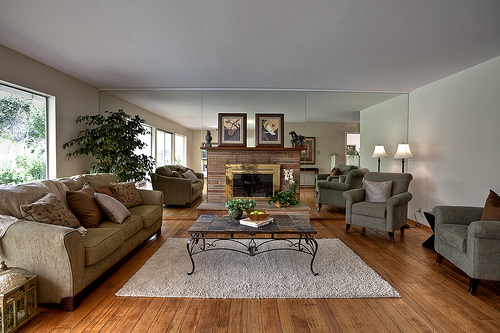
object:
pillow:
[20, 193, 82, 229]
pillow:
[110, 182, 144, 208]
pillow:
[364, 179, 392, 202]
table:
[186, 214, 318, 276]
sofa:
[0, 173, 164, 313]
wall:
[190, 122, 363, 194]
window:
[0, 81, 55, 190]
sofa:
[150, 164, 204, 208]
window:
[126, 119, 186, 190]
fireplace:
[199, 147, 307, 204]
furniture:
[2, 113, 499, 333]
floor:
[139, 206, 438, 330]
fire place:
[225, 163, 281, 203]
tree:
[62, 108, 157, 183]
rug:
[113, 237, 401, 299]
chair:
[342, 172, 413, 243]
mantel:
[200, 147, 307, 151]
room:
[0, 1, 497, 331]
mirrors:
[98, 88, 407, 218]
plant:
[225, 197, 256, 219]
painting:
[218, 113, 247, 148]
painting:
[254, 113, 284, 148]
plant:
[268, 178, 299, 208]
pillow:
[66, 183, 104, 228]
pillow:
[93, 192, 131, 224]